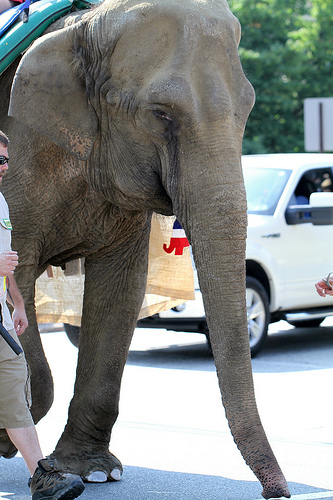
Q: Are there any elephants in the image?
A: Yes, there is an elephant.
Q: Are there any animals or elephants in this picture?
A: Yes, there is an elephant.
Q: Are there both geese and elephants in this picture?
A: No, there is an elephant but no geese.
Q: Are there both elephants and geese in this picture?
A: No, there is an elephant but no geese.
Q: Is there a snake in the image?
A: No, there are no snakes.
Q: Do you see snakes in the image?
A: No, there are no snakes.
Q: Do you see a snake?
A: No, there are no snakes.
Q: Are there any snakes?
A: No, there are no snakes.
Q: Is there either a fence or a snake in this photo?
A: No, there are no snakes or fences.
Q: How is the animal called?
A: The animal is an elephant.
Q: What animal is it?
A: The animal is an elephant.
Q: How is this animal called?
A: This is an elephant.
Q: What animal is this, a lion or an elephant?
A: This is an elephant.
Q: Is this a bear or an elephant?
A: This is an elephant.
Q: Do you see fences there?
A: No, there are no fences.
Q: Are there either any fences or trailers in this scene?
A: No, there are no fences or trailers.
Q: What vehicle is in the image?
A: The vehicle is a car.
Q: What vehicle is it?
A: The vehicle is a car.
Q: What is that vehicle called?
A: That is a car.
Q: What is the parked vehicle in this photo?
A: The vehicle is a car.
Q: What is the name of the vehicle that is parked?
A: The vehicle is a car.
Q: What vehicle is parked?
A: The vehicle is a car.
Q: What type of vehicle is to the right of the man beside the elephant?
A: The vehicle is a car.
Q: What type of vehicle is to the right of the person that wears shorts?
A: The vehicle is a car.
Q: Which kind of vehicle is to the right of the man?
A: The vehicle is a car.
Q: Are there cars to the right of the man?
A: Yes, there is a car to the right of the man.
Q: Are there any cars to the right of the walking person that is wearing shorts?
A: Yes, there is a car to the right of the man.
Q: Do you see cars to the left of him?
A: No, the car is to the right of the man.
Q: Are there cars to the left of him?
A: No, the car is to the right of the man.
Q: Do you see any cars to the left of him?
A: No, the car is to the right of the man.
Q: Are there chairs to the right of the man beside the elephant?
A: No, there is a car to the right of the man.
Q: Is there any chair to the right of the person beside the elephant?
A: No, there is a car to the right of the man.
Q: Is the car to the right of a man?
A: Yes, the car is to the right of a man.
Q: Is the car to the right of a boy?
A: No, the car is to the right of a man.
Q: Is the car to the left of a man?
A: No, the car is to the right of a man.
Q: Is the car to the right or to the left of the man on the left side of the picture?
A: The car is to the right of the man.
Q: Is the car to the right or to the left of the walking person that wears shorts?
A: The car is to the right of the man.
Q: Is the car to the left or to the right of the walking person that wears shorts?
A: The car is to the right of the man.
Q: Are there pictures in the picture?
A: No, there are no pictures.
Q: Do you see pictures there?
A: No, there are no pictures.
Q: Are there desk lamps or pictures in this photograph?
A: No, there are no pictures or desk lamps.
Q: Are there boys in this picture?
A: No, there are no boys.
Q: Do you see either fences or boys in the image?
A: No, there are no boys or fences.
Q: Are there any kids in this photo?
A: No, there are no kids.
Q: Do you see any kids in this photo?
A: No, there are no kids.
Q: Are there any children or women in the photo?
A: No, there are no children or women.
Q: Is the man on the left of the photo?
A: Yes, the man is on the left of the image.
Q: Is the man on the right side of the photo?
A: No, the man is on the left of the image.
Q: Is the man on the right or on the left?
A: The man is on the left of the image.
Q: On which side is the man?
A: The man is on the left of the image.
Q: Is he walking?
A: Yes, the man is walking.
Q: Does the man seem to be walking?
A: Yes, the man is walking.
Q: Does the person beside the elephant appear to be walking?
A: Yes, the man is walking.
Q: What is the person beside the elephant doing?
A: The man is walking.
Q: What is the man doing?
A: The man is walking.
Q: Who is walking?
A: The man is walking.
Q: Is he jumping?
A: No, the man is walking.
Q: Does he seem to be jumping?
A: No, the man is walking.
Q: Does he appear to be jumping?
A: No, the man is walking.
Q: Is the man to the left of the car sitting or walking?
A: The man is walking.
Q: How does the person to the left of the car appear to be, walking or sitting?
A: The man is walking.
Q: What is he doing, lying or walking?
A: The man is walking.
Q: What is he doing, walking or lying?
A: The man is walking.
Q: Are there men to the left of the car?
A: Yes, there is a man to the left of the car.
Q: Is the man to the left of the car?
A: Yes, the man is to the left of the car.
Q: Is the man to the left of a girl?
A: No, the man is to the left of the car.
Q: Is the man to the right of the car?
A: No, the man is to the left of the car.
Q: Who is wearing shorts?
A: The man is wearing shorts.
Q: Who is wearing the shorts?
A: The man is wearing shorts.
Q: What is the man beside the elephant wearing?
A: The man is wearing shorts.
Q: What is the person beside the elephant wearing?
A: The man is wearing shorts.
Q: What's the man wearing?
A: The man is wearing shorts.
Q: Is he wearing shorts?
A: Yes, the man is wearing shorts.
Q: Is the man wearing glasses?
A: No, the man is wearing shorts.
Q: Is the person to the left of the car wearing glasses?
A: No, the man is wearing shorts.